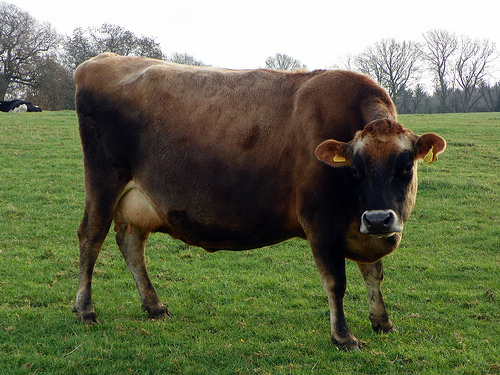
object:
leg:
[359, 260, 391, 318]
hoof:
[140, 302, 170, 319]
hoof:
[369, 324, 401, 337]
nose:
[359, 209, 399, 230]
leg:
[73, 184, 131, 298]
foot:
[327, 329, 361, 351]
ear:
[414, 129, 448, 165]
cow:
[71, 50, 448, 353]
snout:
[355, 205, 407, 235]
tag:
[419, 145, 433, 163]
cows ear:
[415, 130, 448, 165]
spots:
[389, 128, 416, 158]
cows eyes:
[400, 163, 420, 175]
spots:
[234, 122, 269, 155]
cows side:
[70, 53, 379, 253]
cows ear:
[313, 137, 347, 168]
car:
[0, 98, 43, 114]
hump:
[296, 70, 398, 120]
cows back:
[76, 51, 372, 120]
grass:
[0, 108, 499, 374]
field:
[0, 109, 499, 373]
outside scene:
[0, 0, 499, 374]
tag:
[331, 153, 349, 165]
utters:
[112, 190, 162, 234]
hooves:
[70, 302, 100, 324]